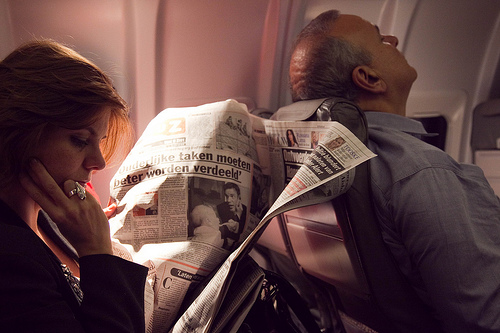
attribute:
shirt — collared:
[358, 107, 498, 329]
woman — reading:
[10, 46, 142, 328]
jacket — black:
[7, 220, 110, 322]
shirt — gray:
[366, 111, 498, 311]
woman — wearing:
[0, 37, 141, 331]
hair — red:
[16, 24, 137, 155]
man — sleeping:
[284, 6, 498, 327]